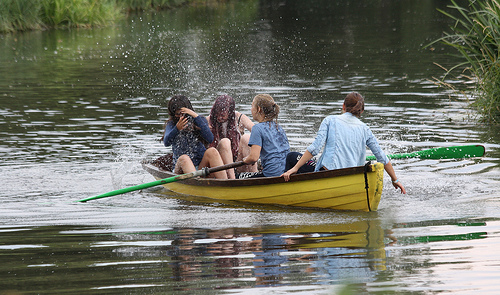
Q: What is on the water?
A: A boat.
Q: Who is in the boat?
A: The girls.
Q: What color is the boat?
A: Yellow.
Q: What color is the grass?
A: Green.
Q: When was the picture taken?
A: Daytime.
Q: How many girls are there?
A: Four.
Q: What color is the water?
A: Gray.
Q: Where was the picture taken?
A: In the water.